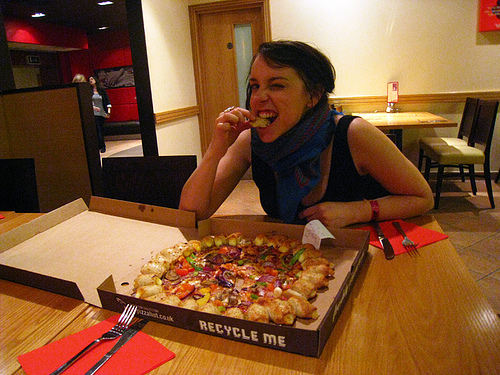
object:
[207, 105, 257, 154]
hand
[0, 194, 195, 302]
lid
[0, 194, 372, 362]
box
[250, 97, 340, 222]
scarf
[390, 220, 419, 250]
fork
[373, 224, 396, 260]
knife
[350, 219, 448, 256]
red napkin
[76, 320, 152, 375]
knife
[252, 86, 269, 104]
nose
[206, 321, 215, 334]
letter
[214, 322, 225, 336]
letter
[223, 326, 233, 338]
letter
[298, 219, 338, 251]
receipt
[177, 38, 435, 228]
woman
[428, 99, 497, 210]
chair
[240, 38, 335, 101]
hair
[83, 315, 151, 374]
silverware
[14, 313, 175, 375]
napkin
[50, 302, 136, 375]
fork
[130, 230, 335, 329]
pizza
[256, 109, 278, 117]
lips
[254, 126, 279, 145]
chin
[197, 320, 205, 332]
letter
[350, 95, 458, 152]
table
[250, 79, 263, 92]
eye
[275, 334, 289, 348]
letter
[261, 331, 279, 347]
letter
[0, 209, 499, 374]
table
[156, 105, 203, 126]
trim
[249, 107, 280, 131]
mouth